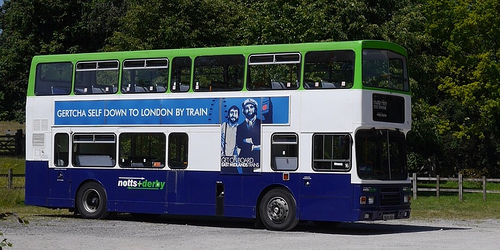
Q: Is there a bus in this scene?
A: Yes, there is a bus.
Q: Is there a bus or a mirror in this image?
A: Yes, there is a bus.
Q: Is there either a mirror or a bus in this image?
A: Yes, there is a bus.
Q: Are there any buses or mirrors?
A: Yes, there is a bus.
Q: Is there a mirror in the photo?
A: No, there are no mirrors.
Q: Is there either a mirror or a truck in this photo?
A: No, there are no mirrors or trucks.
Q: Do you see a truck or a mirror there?
A: No, there are no mirrors or trucks.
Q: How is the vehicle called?
A: The vehicle is a bus.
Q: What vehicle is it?
A: The vehicle is a bus.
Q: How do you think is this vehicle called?
A: That is a bus.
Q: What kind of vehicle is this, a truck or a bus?
A: That is a bus.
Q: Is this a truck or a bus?
A: This is a bus.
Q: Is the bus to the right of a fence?
A: No, the bus is to the left of a fence.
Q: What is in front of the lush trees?
A: The bus is in front of the trees.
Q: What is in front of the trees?
A: The bus is in front of the trees.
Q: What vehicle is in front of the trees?
A: The vehicle is a bus.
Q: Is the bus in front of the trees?
A: Yes, the bus is in front of the trees.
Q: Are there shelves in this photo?
A: No, there are no shelves.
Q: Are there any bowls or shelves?
A: No, there are no shelves or bowls.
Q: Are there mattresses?
A: No, there are no mattresses.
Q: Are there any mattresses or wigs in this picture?
A: No, there are no mattresses or wigs.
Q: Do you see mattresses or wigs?
A: No, there are no mattresses or wigs.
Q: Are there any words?
A: Yes, there are words.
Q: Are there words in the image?
A: Yes, there are words.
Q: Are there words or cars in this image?
A: Yes, there are words.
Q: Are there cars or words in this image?
A: Yes, there are words.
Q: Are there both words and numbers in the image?
A: No, there are words but no numbers.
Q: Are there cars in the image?
A: No, there are no cars.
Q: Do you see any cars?
A: No, there are no cars.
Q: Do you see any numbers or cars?
A: No, there are no cars or numbers.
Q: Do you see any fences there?
A: Yes, there is a fence.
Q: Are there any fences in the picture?
A: Yes, there is a fence.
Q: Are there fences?
A: Yes, there is a fence.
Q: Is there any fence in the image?
A: Yes, there is a fence.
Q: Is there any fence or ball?
A: Yes, there is a fence.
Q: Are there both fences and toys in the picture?
A: No, there is a fence but no toys.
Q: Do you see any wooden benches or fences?
A: Yes, there is a wood fence.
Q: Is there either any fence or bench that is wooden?
A: Yes, the fence is wooden.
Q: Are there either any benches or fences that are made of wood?
A: Yes, the fence is made of wood.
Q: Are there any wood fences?
A: Yes, there is a fence that is made of wood.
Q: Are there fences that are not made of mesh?
A: Yes, there is a fence that is made of wood.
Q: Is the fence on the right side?
A: Yes, the fence is on the right of the image.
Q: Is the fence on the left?
A: No, the fence is on the right of the image.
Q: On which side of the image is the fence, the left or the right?
A: The fence is on the right of the image.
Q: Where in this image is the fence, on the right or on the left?
A: The fence is on the right of the image.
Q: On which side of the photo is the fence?
A: The fence is on the right of the image.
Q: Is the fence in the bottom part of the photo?
A: Yes, the fence is in the bottom of the image.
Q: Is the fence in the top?
A: No, the fence is in the bottom of the image.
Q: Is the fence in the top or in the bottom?
A: The fence is in the bottom of the image.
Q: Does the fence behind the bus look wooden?
A: Yes, the fence is wooden.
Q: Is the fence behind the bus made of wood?
A: Yes, the fence is made of wood.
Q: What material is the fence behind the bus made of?
A: The fence is made of wood.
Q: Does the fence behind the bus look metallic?
A: No, the fence is wooden.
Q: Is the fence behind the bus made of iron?
A: No, the fence is made of wood.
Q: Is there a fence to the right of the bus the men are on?
A: Yes, there is a fence to the right of the bus.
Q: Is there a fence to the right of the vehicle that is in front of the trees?
A: Yes, there is a fence to the right of the bus.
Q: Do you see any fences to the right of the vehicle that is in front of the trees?
A: Yes, there is a fence to the right of the bus.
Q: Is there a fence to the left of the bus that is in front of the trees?
A: No, the fence is to the right of the bus.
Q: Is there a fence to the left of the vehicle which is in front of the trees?
A: No, the fence is to the right of the bus.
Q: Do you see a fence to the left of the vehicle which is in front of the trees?
A: No, the fence is to the right of the bus.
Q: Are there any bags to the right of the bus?
A: No, there is a fence to the right of the bus.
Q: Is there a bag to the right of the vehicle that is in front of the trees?
A: No, there is a fence to the right of the bus.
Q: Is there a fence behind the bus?
A: Yes, there is a fence behind the bus.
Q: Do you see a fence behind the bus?
A: Yes, there is a fence behind the bus.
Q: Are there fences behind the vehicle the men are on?
A: Yes, there is a fence behind the bus.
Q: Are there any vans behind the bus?
A: No, there is a fence behind the bus.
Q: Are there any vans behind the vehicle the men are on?
A: No, there is a fence behind the bus.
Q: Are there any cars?
A: No, there are no cars.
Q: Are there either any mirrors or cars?
A: No, there are no cars or mirrors.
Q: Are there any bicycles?
A: No, there are no bicycles.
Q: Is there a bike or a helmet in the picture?
A: No, there are no bikes or helmets.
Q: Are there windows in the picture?
A: Yes, there is a window.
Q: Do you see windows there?
A: Yes, there is a window.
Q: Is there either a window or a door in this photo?
A: Yes, there is a window.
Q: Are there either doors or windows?
A: Yes, there is a window.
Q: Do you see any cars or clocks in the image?
A: No, there are no cars or clocks.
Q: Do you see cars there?
A: No, there are no cars.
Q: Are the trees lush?
A: Yes, the trees are lush.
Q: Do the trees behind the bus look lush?
A: Yes, the trees are lush.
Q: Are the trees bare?
A: No, the trees are lush.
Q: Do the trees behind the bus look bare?
A: No, the trees are lush.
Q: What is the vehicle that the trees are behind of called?
A: The vehicle is a bus.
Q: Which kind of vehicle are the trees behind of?
A: The trees are behind the bus.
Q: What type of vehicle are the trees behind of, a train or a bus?
A: The trees are behind a bus.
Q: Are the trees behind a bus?
A: Yes, the trees are behind a bus.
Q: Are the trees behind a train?
A: No, the trees are behind a bus.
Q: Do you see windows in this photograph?
A: Yes, there are windows.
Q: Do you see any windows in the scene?
A: Yes, there are windows.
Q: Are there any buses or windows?
A: Yes, there are windows.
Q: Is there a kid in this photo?
A: No, there are no children.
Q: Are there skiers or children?
A: No, there are no children or skiers.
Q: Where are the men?
A: The men are on the bus.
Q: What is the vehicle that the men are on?
A: The vehicle is a bus.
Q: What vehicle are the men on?
A: The men are on the bus.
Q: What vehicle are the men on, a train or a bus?
A: The men are on a bus.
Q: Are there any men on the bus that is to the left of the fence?
A: Yes, there are men on the bus.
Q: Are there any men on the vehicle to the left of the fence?
A: Yes, there are men on the bus.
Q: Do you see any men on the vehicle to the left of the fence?
A: Yes, there are men on the bus.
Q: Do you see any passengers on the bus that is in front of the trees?
A: No, there are men on the bus.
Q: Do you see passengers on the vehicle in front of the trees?
A: No, there are men on the bus.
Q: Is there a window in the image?
A: Yes, there are windows.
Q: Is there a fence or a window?
A: Yes, there are windows.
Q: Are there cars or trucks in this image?
A: No, there are no cars or trucks.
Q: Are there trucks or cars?
A: No, there are no cars or trucks.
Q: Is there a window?
A: Yes, there is a window.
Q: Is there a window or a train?
A: Yes, there is a window.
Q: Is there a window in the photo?
A: Yes, there are windows.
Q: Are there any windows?
A: Yes, there are windows.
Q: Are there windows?
A: Yes, there are windows.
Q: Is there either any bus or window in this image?
A: Yes, there are windows.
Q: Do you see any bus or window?
A: Yes, there are windows.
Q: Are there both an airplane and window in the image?
A: No, there are windows but no airplanes.